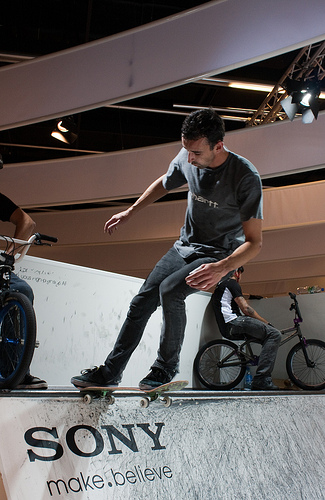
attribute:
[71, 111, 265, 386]
man — performing a trick, looking down, leaning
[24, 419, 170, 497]
advertisement — black, for sony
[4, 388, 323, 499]
ramp — worn, indoors, scarred, scuffed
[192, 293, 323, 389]
bicycle — gray, black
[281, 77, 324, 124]
lighting — overhead, on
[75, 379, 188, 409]
skateboard — brown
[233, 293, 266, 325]
arm — tattooed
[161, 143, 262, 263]
shirt — grey, t-shirt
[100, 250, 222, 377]
jeans — grey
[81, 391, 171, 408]
wheels — white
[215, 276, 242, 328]
shirt — black, white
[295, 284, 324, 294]
bottle — water bottle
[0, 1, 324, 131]
beam — white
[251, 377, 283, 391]
shoe — black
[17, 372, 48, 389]
shoe — black, white